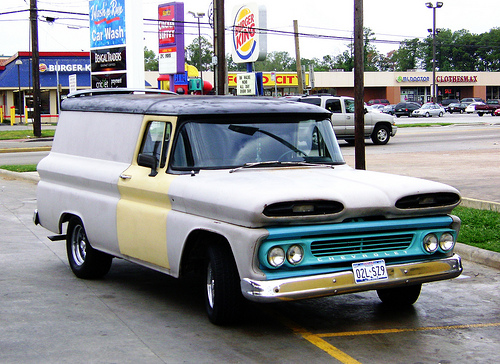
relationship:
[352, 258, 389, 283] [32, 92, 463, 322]
plate on truck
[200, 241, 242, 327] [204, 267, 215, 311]
tire with rim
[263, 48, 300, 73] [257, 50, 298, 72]
leaves on tree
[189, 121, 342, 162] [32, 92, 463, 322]
windshield on truck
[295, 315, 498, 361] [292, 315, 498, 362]
yellow line on parking space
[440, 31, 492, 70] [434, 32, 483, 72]
green leaves on tree